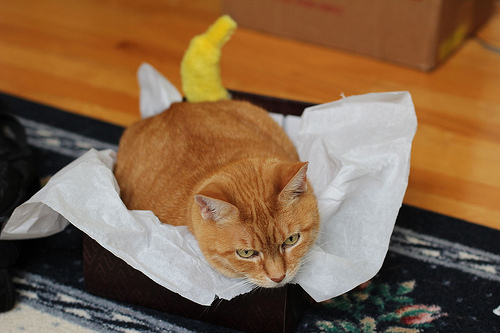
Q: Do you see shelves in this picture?
A: No, there are no shelves.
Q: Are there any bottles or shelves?
A: No, there are no shelves or bottles.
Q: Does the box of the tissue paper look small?
A: Yes, the box is small.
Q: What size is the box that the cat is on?
A: The box is small.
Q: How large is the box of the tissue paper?
A: The box is small.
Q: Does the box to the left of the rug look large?
A: No, the box is small.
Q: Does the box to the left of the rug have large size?
A: No, the box is small.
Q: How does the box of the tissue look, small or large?
A: The box is small.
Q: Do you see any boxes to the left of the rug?
A: Yes, there is a box to the left of the rug.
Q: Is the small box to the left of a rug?
A: Yes, the box is to the left of a rug.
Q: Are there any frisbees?
A: No, there are no frisbees.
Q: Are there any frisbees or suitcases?
A: No, there are no frisbees or suitcases.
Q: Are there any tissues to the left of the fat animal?
A: Yes, there is a tissue to the left of the cat.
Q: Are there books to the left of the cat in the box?
A: No, there is a tissue to the left of the cat.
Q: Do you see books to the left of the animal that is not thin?
A: No, there is a tissue to the left of the cat.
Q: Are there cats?
A: Yes, there is a cat.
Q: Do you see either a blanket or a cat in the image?
A: Yes, there is a cat.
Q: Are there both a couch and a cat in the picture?
A: No, there is a cat but no couches.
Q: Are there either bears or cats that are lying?
A: Yes, the cat is lying.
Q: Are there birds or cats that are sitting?
A: Yes, the cat is sitting.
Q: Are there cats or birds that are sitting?
A: Yes, the cat is sitting.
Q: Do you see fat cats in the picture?
A: Yes, there is a fat cat.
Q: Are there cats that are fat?
A: Yes, there is a cat that is fat.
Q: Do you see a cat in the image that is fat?
A: Yes, there is a cat that is fat.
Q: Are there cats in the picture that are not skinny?
A: Yes, there is a fat cat.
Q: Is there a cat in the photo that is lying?
A: Yes, there is a cat that is lying.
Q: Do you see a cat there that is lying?
A: Yes, there is a cat that is lying.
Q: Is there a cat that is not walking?
A: Yes, there is a cat that is lying.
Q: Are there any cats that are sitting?
A: Yes, there is a cat that is sitting.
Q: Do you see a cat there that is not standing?
A: Yes, there is a cat that is sitting .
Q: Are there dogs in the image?
A: No, there are no dogs.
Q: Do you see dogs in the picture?
A: No, there are no dogs.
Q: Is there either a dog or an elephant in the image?
A: No, there are no dogs or elephants.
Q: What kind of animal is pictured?
A: The animal is a cat.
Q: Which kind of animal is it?
A: The animal is a cat.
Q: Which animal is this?
A: This is a cat.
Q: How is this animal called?
A: This is a cat.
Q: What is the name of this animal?
A: This is a cat.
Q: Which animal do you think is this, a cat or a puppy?
A: This is a cat.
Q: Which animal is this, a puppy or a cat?
A: This is a cat.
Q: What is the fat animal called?
A: The animal is a cat.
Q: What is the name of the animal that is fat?
A: The animal is a cat.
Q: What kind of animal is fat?
A: The animal is a cat.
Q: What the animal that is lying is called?
A: The animal is a cat.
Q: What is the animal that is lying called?
A: The animal is a cat.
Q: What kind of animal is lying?
A: The animal is a cat.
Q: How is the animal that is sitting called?
A: The animal is a cat.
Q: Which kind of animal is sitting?
A: The animal is a cat.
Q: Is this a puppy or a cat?
A: This is a cat.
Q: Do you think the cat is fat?
A: Yes, the cat is fat.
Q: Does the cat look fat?
A: Yes, the cat is fat.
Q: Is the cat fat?
A: Yes, the cat is fat.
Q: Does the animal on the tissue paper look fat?
A: Yes, the cat is fat.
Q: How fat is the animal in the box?
A: The cat is fat.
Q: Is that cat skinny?
A: No, the cat is fat.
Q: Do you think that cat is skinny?
A: No, the cat is fat.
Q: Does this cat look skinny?
A: No, the cat is fat.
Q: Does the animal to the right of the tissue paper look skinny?
A: No, the cat is fat.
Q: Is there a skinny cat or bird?
A: No, there is a cat but it is fat.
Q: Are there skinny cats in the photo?
A: No, there is a cat but it is fat.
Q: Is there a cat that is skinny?
A: No, there is a cat but it is fat.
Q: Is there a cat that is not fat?
A: No, there is a cat but it is fat.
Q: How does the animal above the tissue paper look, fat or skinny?
A: The cat is fat.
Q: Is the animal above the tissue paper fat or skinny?
A: The cat is fat.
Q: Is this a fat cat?
A: Yes, this is a fat cat.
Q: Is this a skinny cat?
A: No, this is a fat cat.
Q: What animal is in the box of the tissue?
A: The cat is in the box.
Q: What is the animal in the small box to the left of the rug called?
A: The animal is a cat.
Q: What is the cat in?
A: The cat is in the box.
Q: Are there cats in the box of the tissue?
A: Yes, there is a cat in the box.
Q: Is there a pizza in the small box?
A: No, there is a cat in the box.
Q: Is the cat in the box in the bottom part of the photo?
A: Yes, the cat is in the box.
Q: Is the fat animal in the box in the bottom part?
A: Yes, the cat is in the box.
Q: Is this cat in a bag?
A: No, the cat is in the box.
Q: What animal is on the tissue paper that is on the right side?
A: The cat is on the tissue.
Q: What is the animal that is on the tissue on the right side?
A: The animal is a cat.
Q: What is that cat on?
A: The cat is on the tissue paper.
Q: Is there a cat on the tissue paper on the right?
A: Yes, there is a cat on the tissue.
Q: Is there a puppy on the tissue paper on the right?
A: No, there is a cat on the tissue.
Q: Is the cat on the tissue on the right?
A: Yes, the cat is on the tissue paper.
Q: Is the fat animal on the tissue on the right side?
A: Yes, the cat is on the tissue paper.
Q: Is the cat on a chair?
A: No, the cat is on the tissue paper.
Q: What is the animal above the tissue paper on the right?
A: The animal is a cat.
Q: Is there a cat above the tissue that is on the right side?
A: Yes, there is a cat above the tissue paper.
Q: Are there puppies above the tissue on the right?
A: No, there is a cat above the tissue.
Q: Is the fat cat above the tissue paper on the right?
A: Yes, the cat is above the tissue.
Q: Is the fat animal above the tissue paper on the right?
A: Yes, the cat is above the tissue.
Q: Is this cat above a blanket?
A: No, the cat is above the tissue.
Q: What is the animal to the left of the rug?
A: The animal is a cat.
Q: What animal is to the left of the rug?
A: The animal is a cat.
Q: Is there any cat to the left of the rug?
A: Yes, there is a cat to the left of the rug.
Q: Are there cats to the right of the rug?
A: No, the cat is to the left of the rug.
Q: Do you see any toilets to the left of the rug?
A: No, there is a cat to the left of the rug.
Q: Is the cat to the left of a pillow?
A: No, the cat is to the left of the rug.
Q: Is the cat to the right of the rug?
A: No, the cat is to the left of the rug.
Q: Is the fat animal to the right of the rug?
A: No, the cat is to the left of the rug.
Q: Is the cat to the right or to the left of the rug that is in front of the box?
A: The cat is to the left of the rug.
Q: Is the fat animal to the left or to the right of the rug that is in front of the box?
A: The cat is to the left of the rug.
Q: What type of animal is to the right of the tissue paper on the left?
A: The animal is a cat.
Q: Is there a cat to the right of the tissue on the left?
A: Yes, there is a cat to the right of the tissue.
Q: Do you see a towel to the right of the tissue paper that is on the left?
A: No, there is a cat to the right of the tissue.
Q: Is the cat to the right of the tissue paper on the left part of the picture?
A: Yes, the cat is to the right of the tissue.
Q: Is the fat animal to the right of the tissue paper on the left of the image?
A: Yes, the cat is to the right of the tissue.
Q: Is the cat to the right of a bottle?
A: No, the cat is to the right of the tissue.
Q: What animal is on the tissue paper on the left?
A: The cat is on the tissue paper.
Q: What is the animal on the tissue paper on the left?
A: The animal is a cat.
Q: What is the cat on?
A: The cat is on the tissue paper.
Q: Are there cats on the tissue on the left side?
A: Yes, there is a cat on the tissue.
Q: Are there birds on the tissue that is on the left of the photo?
A: No, there is a cat on the tissue paper.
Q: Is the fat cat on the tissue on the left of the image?
A: Yes, the cat is on the tissue.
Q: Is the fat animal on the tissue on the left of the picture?
A: Yes, the cat is on the tissue.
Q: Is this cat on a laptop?
A: No, the cat is on the tissue.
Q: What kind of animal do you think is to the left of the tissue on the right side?
A: The animal is a cat.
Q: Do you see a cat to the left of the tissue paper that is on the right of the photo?
A: Yes, there is a cat to the left of the tissue.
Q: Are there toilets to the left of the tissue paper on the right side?
A: No, there is a cat to the left of the tissue paper.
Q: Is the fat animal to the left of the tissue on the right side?
A: Yes, the cat is to the left of the tissue.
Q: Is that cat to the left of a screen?
A: No, the cat is to the left of the tissue.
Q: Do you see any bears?
A: No, there are no bears.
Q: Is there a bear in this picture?
A: No, there are no bears.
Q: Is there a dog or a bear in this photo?
A: No, there are no bears or dogs.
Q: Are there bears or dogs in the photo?
A: No, there are no bears or dogs.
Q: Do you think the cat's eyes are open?
A: Yes, the eyes are open.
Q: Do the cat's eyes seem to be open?
A: Yes, the eyes are open.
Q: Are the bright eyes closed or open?
A: The eyes are open.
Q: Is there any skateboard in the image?
A: No, there are no skateboards.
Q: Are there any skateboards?
A: No, there are no skateboards.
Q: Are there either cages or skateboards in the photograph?
A: No, there are no skateboards or cages.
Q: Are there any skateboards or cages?
A: No, there are no skateboards or cages.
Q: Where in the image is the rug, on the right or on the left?
A: The rug is on the right of the image.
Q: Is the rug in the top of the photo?
A: No, the rug is in the bottom of the image.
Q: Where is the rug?
A: The rug is on the floor.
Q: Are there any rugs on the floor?
A: Yes, there is a rug on the floor.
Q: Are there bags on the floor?
A: No, there is a rug on the floor.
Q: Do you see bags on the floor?
A: No, there is a rug on the floor.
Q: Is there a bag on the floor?
A: No, there is a rug on the floor.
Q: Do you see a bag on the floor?
A: No, there is a rug on the floor.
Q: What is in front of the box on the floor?
A: The rug is in front of the box.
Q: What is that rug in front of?
A: The rug is in front of the box.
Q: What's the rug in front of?
A: The rug is in front of the box.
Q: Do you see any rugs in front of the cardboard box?
A: Yes, there is a rug in front of the box.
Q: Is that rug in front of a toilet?
A: No, the rug is in front of the box.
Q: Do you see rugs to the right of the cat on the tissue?
A: Yes, there is a rug to the right of the cat.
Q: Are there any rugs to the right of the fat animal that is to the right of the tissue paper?
A: Yes, there is a rug to the right of the cat.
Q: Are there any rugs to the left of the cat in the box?
A: No, the rug is to the right of the cat.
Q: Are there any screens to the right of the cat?
A: No, there is a rug to the right of the cat.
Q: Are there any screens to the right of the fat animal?
A: No, there is a rug to the right of the cat.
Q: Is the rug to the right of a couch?
A: No, the rug is to the right of a cat.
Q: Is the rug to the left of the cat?
A: No, the rug is to the right of the cat.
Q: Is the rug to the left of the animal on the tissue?
A: No, the rug is to the right of the cat.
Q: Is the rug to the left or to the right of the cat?
A: The rug is to the right of the cat.